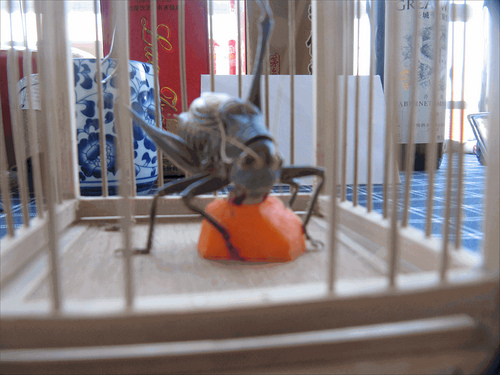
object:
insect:
[128, 85, 326, 192]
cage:
[0, 0, 499, 375]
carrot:
[197, 193, 307, 261]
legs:
[162, 175, 203, 265]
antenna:
[209, 110, 281, 177]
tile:
[460, 219, 479, 235]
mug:
[75, 89, 101, 160]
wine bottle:
[420, 147, 427, 166]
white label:
[376, 2, 453, 143]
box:
[98, 0, 222, 177]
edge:
[279, 227, 304, 251]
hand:
[217, 218, 230, 259]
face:
[226, 145, 271, 201]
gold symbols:
[296, 5, 324, 76]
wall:
[249, 8, 259, 22]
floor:
[424, 181, 477, 228]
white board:
[203, 74, 386, 184]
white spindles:
[309, 14, 333, 62]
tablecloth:
[451, 227, 470, 241]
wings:
[180, 118, 208, 161]